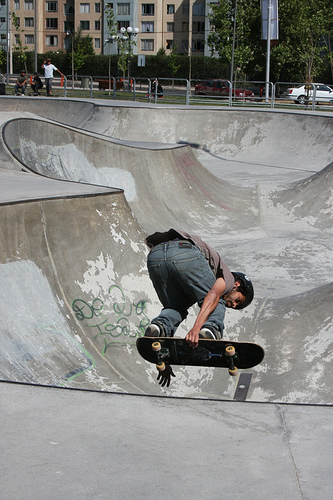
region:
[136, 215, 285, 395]
Skateboarder going down the ramp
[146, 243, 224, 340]
Jeans with tennis shoes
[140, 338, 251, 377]
Four wheels on a skateboard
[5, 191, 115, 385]
Cement ramp with graffiti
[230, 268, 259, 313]
Man wearing a black helmet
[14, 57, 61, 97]
Three men watching the skateboarder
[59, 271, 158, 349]
Graffiti on the skateboard ramp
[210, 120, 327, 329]
Weathered looking concrete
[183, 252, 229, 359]
Man is holding on to skateboard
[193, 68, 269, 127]
Red car parked on side of road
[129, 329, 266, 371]
bottom of a skateboard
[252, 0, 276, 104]
back of a street sign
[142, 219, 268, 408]
a boy riding a skateboard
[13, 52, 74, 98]
people watching boy skateboarding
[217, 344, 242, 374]
wheels on a skateboard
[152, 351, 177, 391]
boy's hand hanging under skateboard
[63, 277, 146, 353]
grafitti on the cement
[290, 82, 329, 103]
a parked white car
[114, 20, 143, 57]
3 globe street lamp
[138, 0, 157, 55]
windows in a building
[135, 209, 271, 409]
the boy is skateboarding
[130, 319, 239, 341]
the soles of his sneakers are white & grey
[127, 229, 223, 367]
He is wearing jeans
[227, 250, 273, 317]
his helmet is black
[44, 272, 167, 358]
graffitti is on the wall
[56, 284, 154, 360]
the graffitti is written in green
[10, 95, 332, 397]
this skatepark has some complex paths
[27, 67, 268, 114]
the place is enclosed by a fence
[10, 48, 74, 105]
several people are watching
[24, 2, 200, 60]
apartment buildings are in the background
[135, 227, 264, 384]
Man doing a trick on a skateboard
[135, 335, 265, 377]
Black skateboard with yellow wheels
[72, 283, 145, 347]
Green graffiti on concrete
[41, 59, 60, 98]
Skater in white shirt waiting with board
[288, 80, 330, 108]
White car outside skate park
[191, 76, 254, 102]
Red sedan outside skate park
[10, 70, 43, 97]
Skaters sitting and resting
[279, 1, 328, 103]
Tree outside skate park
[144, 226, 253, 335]
Man in jeans bent over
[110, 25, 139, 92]
Street lamps with white globes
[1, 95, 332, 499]
Skateboard park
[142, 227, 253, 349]
Skateboarder performing in a skateboard park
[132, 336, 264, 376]
Skateboard in the air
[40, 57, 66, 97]
Man holding a skateboard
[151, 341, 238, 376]
Wheels of the skateboard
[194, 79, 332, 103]
Cars on the road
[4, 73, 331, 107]
Metal fence around the skateboard park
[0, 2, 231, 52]
Buildings in the background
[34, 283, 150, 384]
Graffiti on the concrete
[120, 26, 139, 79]
Street lights on the black pole